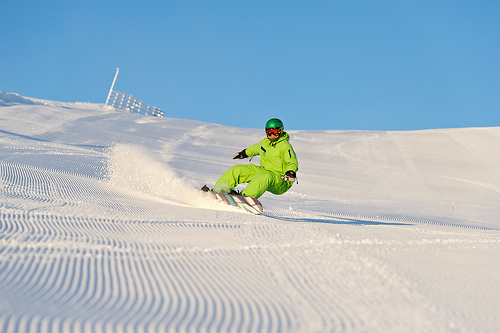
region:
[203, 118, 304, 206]
a man in a green snow suit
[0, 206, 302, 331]
a fresh mountain of snow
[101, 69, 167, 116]
a white fence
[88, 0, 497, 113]
a clear blue sky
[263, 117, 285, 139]
a dark green helmet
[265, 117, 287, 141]
a man in dark red goggles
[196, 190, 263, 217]
a multicolored snowboard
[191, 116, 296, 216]
a snowboarding riding on the edge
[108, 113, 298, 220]
a snowboarder kicking up powder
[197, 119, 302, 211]
a snowboarder in a green jacket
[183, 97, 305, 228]
a person snowboarding in the snow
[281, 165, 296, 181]
a black and white nylon glove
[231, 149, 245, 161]
a black and white nylon glove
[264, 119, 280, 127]
a green helmet on a head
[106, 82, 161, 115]
a partial white fence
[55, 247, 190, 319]
treads in the white snow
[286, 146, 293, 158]
a black zipper on a sleeve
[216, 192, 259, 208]
a colorful snowboard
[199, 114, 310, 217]
a person wearing a neon green snowsuit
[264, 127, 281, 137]
orange snow googles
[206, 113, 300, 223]
man wearing bright green snowsuit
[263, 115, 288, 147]
man wearing bright green helmet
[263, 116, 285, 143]
man wearing orange reflective sungoggles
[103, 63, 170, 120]
white fencing against white snow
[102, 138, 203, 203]
snow being kicked up in air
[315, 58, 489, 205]
snowy hill against blue sky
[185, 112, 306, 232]
one sunlit crouching snowboarder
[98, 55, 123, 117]
This is a pole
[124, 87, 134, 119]
This is a pole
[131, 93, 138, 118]
This is a pole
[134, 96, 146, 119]
This is a pole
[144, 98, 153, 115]
This is a pole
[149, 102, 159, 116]
This is a pole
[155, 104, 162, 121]
This is a pole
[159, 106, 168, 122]
This is a pole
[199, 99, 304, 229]
green suited snow boarder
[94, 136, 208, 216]
snow threw up in wake of snow board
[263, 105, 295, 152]
green round helmet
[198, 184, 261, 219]
bottom of snow board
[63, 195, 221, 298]
snow with white grooves in it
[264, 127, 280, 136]
black framed red goggles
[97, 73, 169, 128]
white fence top of hill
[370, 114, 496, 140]
spot where white snow meets blue sky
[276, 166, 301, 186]
white glove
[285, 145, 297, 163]
black zipper arm of green suit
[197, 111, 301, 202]
man leaning on snowboard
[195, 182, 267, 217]
snowboard on top of snow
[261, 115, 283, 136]
snowboarder wearing a helmet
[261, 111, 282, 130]
man's helmet is green